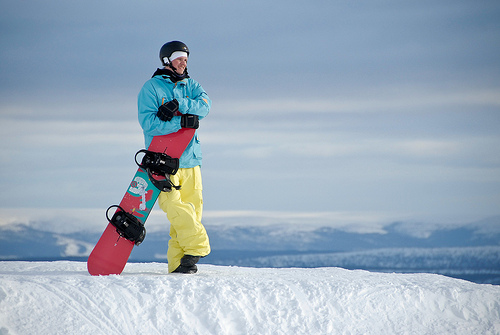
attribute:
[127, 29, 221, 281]
man — blue, white, smiling, happy, looking, yellow, standing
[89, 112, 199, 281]
board — long, red, teal, white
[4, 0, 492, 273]
sky — massive, huge, white, gray, grey, blue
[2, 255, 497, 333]
snow — close